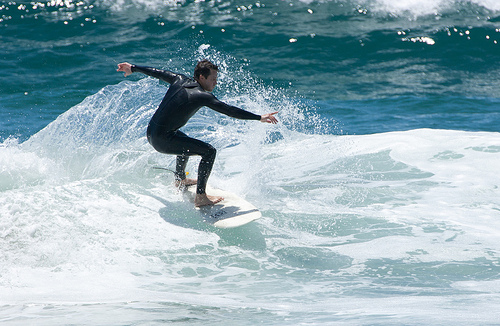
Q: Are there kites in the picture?
A: No, there are no kites.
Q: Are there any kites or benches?
A: No, there are no kites or benches.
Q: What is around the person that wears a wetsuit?
A: The water is around the man.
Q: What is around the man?
A: The water is around the man.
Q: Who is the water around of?
A: The water is around the man.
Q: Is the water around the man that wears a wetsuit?
A: Yes, the water is around the man.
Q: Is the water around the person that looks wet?
A: Yes, the water is around the man.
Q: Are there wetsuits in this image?
A: Yes, there is a wetsuit.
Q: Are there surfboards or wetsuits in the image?
A: Yes, there is a wetsuit.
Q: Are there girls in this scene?
A: No, there are no girls.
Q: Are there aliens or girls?
A: No, there are no girls or aliens.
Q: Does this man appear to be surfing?
A: Yes, the man is surfing.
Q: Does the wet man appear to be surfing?
A: Yes, the man is surfing.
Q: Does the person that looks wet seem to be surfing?
A: Yes, the man is surfing.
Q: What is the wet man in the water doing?
A: The man is surfing.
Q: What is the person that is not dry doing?
A: The man is surfing.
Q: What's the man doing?
A: The man is surfing.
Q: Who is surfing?
A: The man is surfing.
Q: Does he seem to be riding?
A: No, the man is surfing.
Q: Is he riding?
A: No, the man is surfing.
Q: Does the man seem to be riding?
A: No, the man is surfing.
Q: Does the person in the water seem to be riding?
A: No, the man is surfing.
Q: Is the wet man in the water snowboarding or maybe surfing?
A: The man is surfing.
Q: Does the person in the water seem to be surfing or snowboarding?
A: The man is surfing.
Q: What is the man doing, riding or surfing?
A: The man is surfing.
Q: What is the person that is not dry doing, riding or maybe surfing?
A: The man is surfing.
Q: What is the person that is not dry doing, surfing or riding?
A: The man is surfing.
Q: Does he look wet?
A: Yes, the man is wet.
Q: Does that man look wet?
A: Yes, the man is wet.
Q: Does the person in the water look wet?
A: Yes, the man is wet.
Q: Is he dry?
A: No, the man is wet.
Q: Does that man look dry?
A: No, the man is wet.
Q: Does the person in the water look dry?
A: No, the man is wet.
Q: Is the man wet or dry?
A: The man is wet.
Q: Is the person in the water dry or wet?
A: The man is wet.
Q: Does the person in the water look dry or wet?
A: The man is wet.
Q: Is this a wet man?
A: Yes, this is a wet man.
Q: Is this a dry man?
A: No, this is a wet man.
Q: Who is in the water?
A: The man is in the water.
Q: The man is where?
A: The man is in the water.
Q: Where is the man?
A: The man is in the water.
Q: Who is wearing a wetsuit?
A: The man is wearing a wetsuit.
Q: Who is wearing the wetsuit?
A: The man is wearing a wetsuit.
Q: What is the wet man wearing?
A: The man is wearing a wetsuit.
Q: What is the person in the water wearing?
A: The man is wearing a wetsuit.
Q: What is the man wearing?
A: The man is wearing a wetsuit.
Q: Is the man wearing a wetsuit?
A: Yes, the man is wearing a wetsuit.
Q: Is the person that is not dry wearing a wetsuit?
A: Yes, the man is wearing a wetsuit.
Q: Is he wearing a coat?
A: No, the man is wearing a wetsuit.